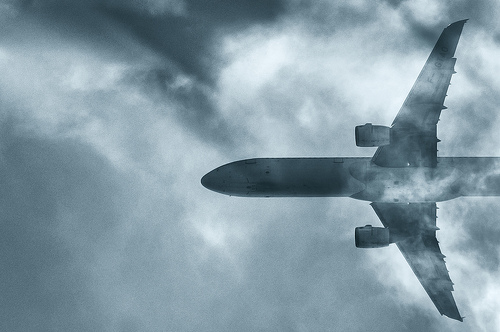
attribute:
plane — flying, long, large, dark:
[202, 8, 499, 325]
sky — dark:
[9, 13, 342, 136]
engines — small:
[354, 124, 402, 248]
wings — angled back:
[377, 20, 468, 323]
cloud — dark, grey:
[17, 5, 347, 77]